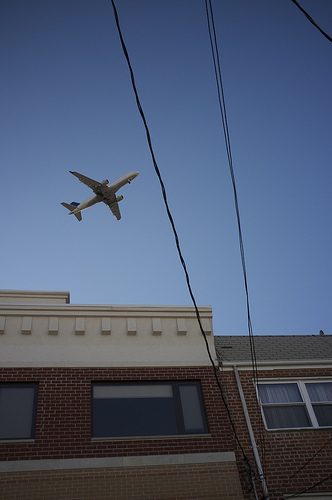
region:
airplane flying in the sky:
[56, 160, 141, 226]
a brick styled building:
[2, 286, 242, 498]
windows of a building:
[84, 368, 212, 444]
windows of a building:
[248, 368, 329, 427]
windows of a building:
[0, 374, 41, 448]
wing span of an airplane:
[70, 170, 107, 189]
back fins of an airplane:
[61, 201, 83, 225]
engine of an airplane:
[98, 177, 112, 189]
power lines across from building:
[182, 2, 273, 496]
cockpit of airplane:
[127, 168, 139, 178]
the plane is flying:
[36, 155, 150, 249]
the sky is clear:
[39, 216, 85, 303]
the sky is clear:
[188, 250, 309, 323]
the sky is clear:
[81, 250, 190, 296]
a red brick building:
[3, 361, 330, 498]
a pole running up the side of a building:
[234, 363, 272, 498]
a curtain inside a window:
[257, 383, 312, 427]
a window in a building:
[91, 379, 180, 432]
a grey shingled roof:
[212, 332, 330, 366]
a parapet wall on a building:
[0, 300, 219, 364]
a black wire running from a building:
[108, 1, 252, 469]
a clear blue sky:
[0, 0, 330, 334]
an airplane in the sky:
[58, 162, 142, 225]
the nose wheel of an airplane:
[126, 177, 132, 185]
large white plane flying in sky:
[54, 162, 144, 230]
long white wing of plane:
[66, 169, 104, 190]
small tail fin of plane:
[58, 199, 76, 210]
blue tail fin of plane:
[65, 200, 83, 207]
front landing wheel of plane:
[128, 178, 131, 185]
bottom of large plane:
[82, 174, 134, 209]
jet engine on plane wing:
[98, 175, 110, 186]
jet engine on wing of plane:
[109, 189, 124, 211]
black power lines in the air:
[150, 122, 235, 261]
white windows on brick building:
[251, 375, 328, 437]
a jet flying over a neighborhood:
[52, 160, 313, 448]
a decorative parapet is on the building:
[1, 289, 214, 369]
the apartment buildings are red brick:
[4, 334, 329, 498]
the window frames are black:
[2, 377, 205, 443]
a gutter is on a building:
[216, 356, 330, 499]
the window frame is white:
[251, 372, 331, 429]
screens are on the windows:
[259, 400, 330, 431]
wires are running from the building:
[109, 3, 331, 499]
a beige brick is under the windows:
[2, 417, 241, 496]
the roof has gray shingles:
[214, 330, 330, 361]